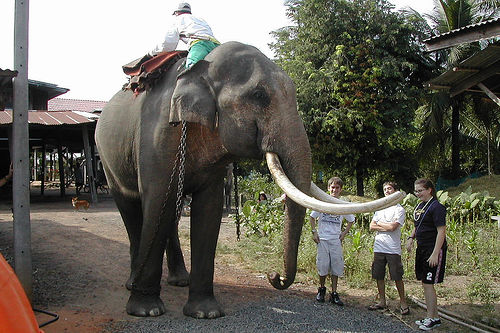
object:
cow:
[305, 173, 352, 308]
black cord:
[33, 304, 62, 328]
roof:
[421, 18, 498, 56]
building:
[419, 16, 500, 108]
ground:
[441, 108, 466, 132]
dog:
[72, 196, 91, 214]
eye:
[251, 90, 264, 100]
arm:
[344, 215, 354, 232]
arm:
[309, 212, 319, 233]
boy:
[308, 176, 356, 306]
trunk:
[265, 114, 313, 290]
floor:
[252, 166, 276, 183]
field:
[49, 169, 481, 330]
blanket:
[120, 49, 187, 96]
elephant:
[92, 40, 406, 320]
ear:
[168, 70, 216, 129]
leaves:
[339, 43, 371, 135]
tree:
[264, 0, 414, 199]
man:
[147, 3, 219, 71]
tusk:
[309, 183, 407, 214]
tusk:
[266, 153, 405, 215]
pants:
[185, 40, 218, 69]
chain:
[130, 118, 187, 293]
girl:
[405, 176, 445, 331]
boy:
[367, 180, 409, 315]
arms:
[383, 213, 405, 231]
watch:
[312, 229, 318, 232]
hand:
[312, 233, 321, 244]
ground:
[36, 298, 76, 331]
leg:
[132, 159, 181, 298]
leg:
[188, 183, 224, 291]